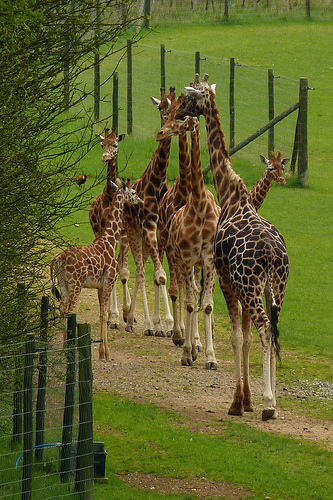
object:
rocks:
[281, 376, 331, 398]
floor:
[291, 207, 319, 254]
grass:
[92, 388, 333, 500]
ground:
[0, 1, 332, 500]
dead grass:
[0, 234, 333, 454]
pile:
[289, 377, 333, 402]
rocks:
[191, 375, 230, 389]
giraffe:
[50, 178, 144, 363]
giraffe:
[156, 92, 221, 369]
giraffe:
[248, 150, 290, 212]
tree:
[0, 0, 161, 436]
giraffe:
[158, 92, 215, 343]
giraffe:
[121, 86, 175, 337]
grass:
[0, 374, 333, 500]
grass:
[37, 184, 332, 378]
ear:
[184, 87, 202, 99]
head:
[95, 128, 126, 163]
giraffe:
[89, 127, 138, 329]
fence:
[29, 14, 315, 186]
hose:
[15, 443, 61, 470]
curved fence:
[9, 296, 94, 500]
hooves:
[228, 392, 275, 422]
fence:
[0, 333, 104, 500]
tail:
[266, 244, 283, 366]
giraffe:
[174, 72, 290, 421]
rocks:
[282, 383, 298, 399]